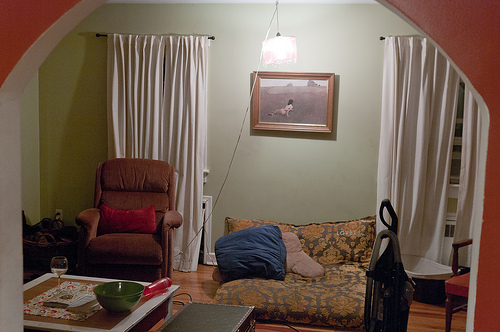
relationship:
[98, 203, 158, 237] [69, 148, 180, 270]
pillow on recliner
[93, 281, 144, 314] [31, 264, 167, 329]
bowl on table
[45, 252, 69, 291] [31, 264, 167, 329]
wine glass on table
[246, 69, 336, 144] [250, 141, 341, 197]
painting on wall